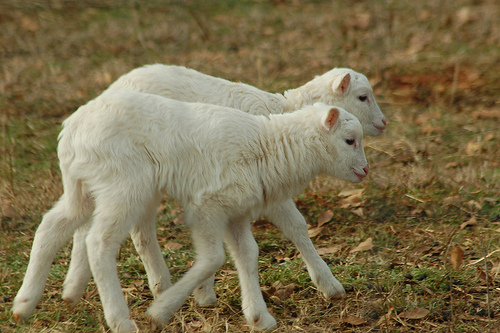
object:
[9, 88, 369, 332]
sheep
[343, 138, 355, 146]
eye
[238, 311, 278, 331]
paw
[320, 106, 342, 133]
ear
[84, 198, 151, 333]
leg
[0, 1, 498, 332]
grass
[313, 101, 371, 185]
head